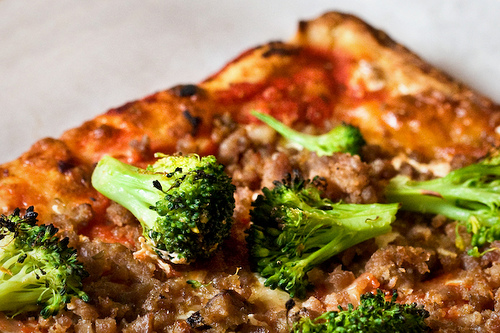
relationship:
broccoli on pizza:
[92, 153, 239, 261] [1, 11, 500, 332]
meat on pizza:
[220, 127, 383, 212] [1, 11, 500, 332]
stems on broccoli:
[91, 153, 158, 207] [92, 153, 239, 261]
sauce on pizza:
[247, 46, 366, 131] [1, 11, 500, 332]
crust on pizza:
[304, 1, 499, 130] [1, 11, 500, 332]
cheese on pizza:
[355, 99, 491, 149] [1, 11, 500, 332]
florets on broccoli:
[186, 161, 236, 202] [92, 153, 239, 261]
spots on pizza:
[167, 83, 204, 98] [1, 11, 500, 332]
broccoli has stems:
[92, 153, 239, 261] [91, 153, 158, 207]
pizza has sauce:
[1, 11, 500, 332] [247, 46, 366, 131]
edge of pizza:
[307, 1, 498, 112] [1, 11, 500, 332]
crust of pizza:
[304, 1, 499, 130] [1, 11, 500, 332]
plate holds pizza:
[1, 2, 500, 160] [1, 11, 500, 332]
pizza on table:
[1, 11, 500, 332] [1, 2, 500, 160]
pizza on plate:
[1, 11, 500, 332] [1, 2, 500, 160]